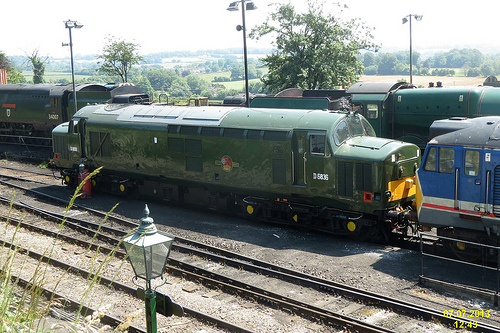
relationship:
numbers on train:
[309, 173, 331, 182] [60, 95, 418, 242]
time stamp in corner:
[434, 305, 499, 332] [431, 289, 499, 331]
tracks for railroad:
[5, 221, 264, 307] [20, 100, 499, 332]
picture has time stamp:
[2, 1, 495, 332] [434, 305, 499, 332]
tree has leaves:
[90, 43, 141, 79] [108, 46, 140, 60]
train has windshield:
[60, 95, 418, 242] [333, 111, 377, 134]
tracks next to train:
[5, 221, 264, 307] [60, 95, 418, 242]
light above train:
[61, 15, 90, 51] [60, 95, 418, 242]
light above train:
[220, 0, 258, 17] [60, 95, 418, 242]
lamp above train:
[400, 16, 410, 27] [370, 83, 499, 137]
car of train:
[62, 110, 410, 236] [60, 95, 418, 242]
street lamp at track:
[131, 212, 167, 332] [5, 221, 264, 307]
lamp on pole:
[61, 16, 87, 31] [67, 31, 87, 116]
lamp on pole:
[220, 0, 263, 12] [240, 14, 257, 95]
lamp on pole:
[400, 9, 425, 27] [405, 22, 418, 82]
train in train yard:
[60, 95, 418, 242] [20, 100, 499, 332]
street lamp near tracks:
[131, 212, 167, 332] [5, 221, 264, 307]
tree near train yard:
[90, 43, 141, 79] [20, 100, 499, 332]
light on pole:
[61, 15, 90, 51] [67, 31, 87, 116]